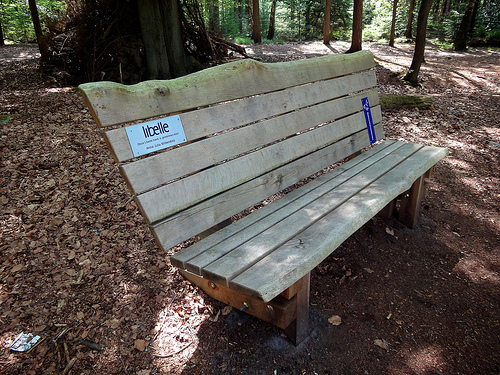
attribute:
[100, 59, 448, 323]
slat — weathered, brown, wood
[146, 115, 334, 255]
slat — wood, brown, weathered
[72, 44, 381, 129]
slat — wood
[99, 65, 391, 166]
slat — wood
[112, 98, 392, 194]
slat — wood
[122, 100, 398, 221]
slat — wood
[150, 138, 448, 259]
slat — wood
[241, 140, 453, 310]
slat — wood